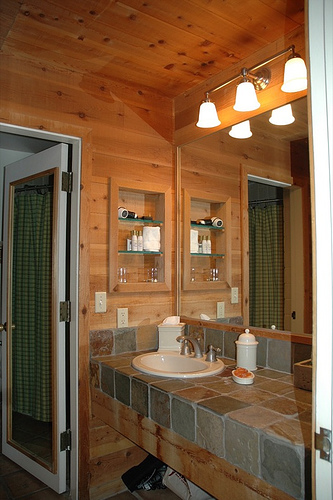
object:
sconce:
[197, 56, 309, 139]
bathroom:
[0, 0, 317, 500]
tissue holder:
[157, 323, 185, 352]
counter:
[90, 318, 315, 500]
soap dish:
[231, 367, 254, 384]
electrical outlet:
[116, 307, 128, 327]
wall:
[0, 0, 314, 499]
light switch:
[95, 292, 106, 313]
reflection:
[240, 164, 291, 332]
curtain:
[12, 175, 51, 422]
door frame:
[0, 127, 82, 500]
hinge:
[61, 171, 72, 193]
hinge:
[59, 301, 70, 322]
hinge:
[60, 428, 71, 451]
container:
[235, 329, 259, 371]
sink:
[131, 350, 224, 379]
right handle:
[205, 345, 217, 361]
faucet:
[176, 335, 203, 359]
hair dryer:
[118, 206, 138, 218]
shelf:
[118, 218, 163, 226]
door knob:
[0, 322, 6, 331]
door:
[1, 142, 70, 488]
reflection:
[231, 287, 238, 303]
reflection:
[216, 301, 224, 318]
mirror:
[177, 95, 313, 339]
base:
[91, 390, 311, 499]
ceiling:
[1, 1, 308, 101]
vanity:
[80, 97, 311, 498]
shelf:
[117, 250, 162, 255]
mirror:
[12, 172, 52, 468]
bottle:
[132, 230, 138, 252]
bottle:
[137, 231, 143, 251]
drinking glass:
[117, 267, 126, 282]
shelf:
[117, 283, 164, 293]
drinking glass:
[147, 268, 158, 283]